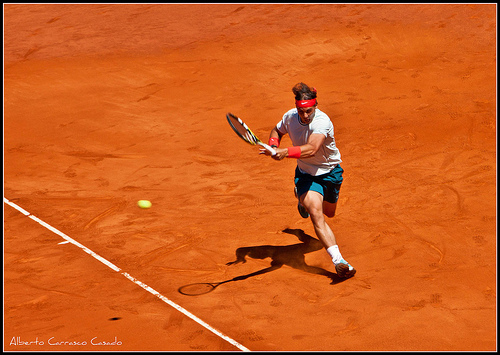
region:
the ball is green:
[76, 128, 310, 285]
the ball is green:
[123, 136, 235, 286]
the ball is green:
[86, 144, 221, 342]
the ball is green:
[116, 86, 188, 214]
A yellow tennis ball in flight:
[124, 177, 179, 232]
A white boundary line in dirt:
[54, 213, 194, 333]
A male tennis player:
[221, 55, 394, 292]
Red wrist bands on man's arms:
[263, 127, 306, 169]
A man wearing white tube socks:
[312, 224, 367, 286]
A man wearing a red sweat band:
[273, 57, 338, 127]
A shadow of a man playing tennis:
[158, 215, 319, 305]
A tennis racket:
[212, 100, 281, 176]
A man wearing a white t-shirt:
[266, 78, 347, 170]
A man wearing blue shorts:
[293, 156, 345, 216]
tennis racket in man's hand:
[202, 98, 274, 163]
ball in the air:
[117, 162, 183, 227]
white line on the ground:
[131, 278, 224, 339]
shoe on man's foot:
[321, 239, 373, 292]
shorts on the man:
[273, 159, 357, 228]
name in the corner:
[13, 332, 117, 354]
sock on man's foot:
[320, 242, 354, 254]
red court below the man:
[335, 217, 437, 287]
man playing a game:
[235, 71, 357, 232]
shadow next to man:
[231, 221, 298, 282]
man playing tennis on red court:
[224, 81, 356, 281]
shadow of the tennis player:
[174, 227, 334, 309]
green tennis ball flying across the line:
[130, 194, 155, 219]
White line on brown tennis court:
[25, 207, 227, 335]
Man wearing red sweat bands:
[264, 80, 321, 165]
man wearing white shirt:
[277, 99, 341, 179]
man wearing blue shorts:
[292, 164, 347, 199]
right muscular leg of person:
[300, 188, 330, 248]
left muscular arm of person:
[270, 135, 325, 155]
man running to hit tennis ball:
[131, 88, 378, 353]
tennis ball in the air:
[117, 184, 173, 232]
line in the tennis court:
[33, 202, 250, 336]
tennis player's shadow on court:
[171, 222, 318, 319]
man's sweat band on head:
[289, 90, 327, 115]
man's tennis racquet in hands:
[208, 107, 313, 180]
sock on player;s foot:
[298, 237, 363, 259]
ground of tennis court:
[355, 125, 457, 325]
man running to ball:
[218, 80, 353, 329]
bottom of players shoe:
[303, 252, 364, 291]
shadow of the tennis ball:
[101, 305, 132, 327]